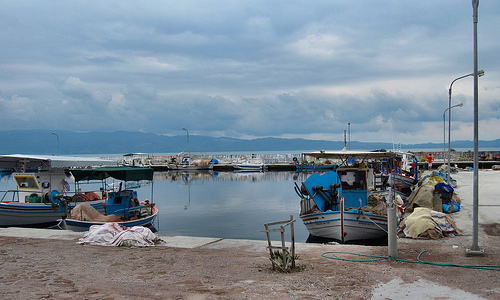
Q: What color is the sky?
A: Gray.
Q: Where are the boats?
A: On the docks.